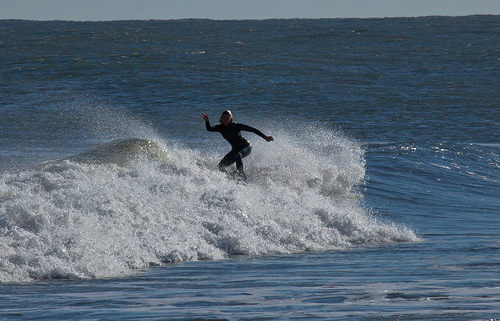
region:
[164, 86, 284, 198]
One person is surfing.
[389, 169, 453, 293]
water is blue color.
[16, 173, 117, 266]
Waves are white color.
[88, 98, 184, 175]
Water is splashing.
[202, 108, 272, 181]
Person is wearing black dress.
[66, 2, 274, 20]
Sky is blue color.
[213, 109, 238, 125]
Person hair is brown color.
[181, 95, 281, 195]
Person is standing in surfing board.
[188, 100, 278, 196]
Person hands are wide apart to get balance.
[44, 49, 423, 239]
Day time picture.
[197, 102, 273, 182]
woman surfing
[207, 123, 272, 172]
black wetsuit of the surfer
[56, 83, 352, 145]
white spray of the wave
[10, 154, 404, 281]
white foam of the wave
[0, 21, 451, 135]
calm waters behind the wave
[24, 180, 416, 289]
wave crashing back into the ocean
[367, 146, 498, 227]
swell of the wave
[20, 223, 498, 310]
ripples in the water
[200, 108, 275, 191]
surfer riding the wave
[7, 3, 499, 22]
gray blue sky above waters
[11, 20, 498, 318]
the ocean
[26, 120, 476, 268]
a wave on the ocean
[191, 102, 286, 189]
a person is surfing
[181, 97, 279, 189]
a woman is surfing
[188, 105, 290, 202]
the surfer is standing on a surfboard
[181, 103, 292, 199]
the woman is balancing on a surfboard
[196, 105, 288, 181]
the woman wears a wet suit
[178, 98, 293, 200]
the surfer wears a black wet suit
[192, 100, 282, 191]
the surfer holds her arms out for balance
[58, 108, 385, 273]
the surfer is riding a wave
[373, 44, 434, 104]
part of a water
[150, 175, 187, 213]
part of a splash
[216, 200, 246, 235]
part of a splash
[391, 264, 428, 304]
[art of a wave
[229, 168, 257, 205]
part of a board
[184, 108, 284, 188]
person is on surfboard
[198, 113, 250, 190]
person has black wetsuit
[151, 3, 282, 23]
sky is light blue and cloudless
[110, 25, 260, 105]
calm water in distance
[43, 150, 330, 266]
large wave around person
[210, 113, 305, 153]
person has arms extended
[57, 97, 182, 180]
person is making wake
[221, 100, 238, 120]
person has dark hair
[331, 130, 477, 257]
blue water behind wave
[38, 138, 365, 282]
wave churning around surfer